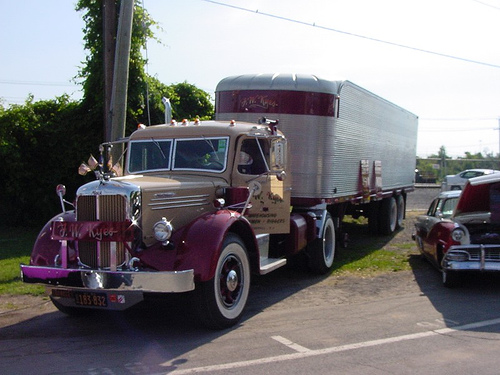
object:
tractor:
[17, 117, 293, 329]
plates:
[72, 291, 108, 308]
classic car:
[411, 172, 500, 289]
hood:
[450, 172, 499, 222]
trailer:
[213, 71, 421, 277]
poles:
[106, 0, 135, 179]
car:
[441, 167, 500, 193]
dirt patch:
[0, 264, 445, 342]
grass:
[1, 240, 417, 299]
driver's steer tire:
[190, 228, 256, 330]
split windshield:
[125, 134, 232, 176]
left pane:
[170, 136, 231, 174]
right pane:
[125, 137, 176, 175]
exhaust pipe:
[160, 96, 174, 126]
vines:
[0, 0, 215, 220]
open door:
[228, 131, 293, 236]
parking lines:
[146, 315, 499, 375]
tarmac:
[1, 290, 500, 375]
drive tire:
[284, 209, 339, 277]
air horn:
[256, 115, 276, 127]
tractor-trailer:
[19, 72, 419, 329]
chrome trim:
[147, 193, 211, 212]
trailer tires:
[367, 196, 397, 236]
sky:
[0, 0, 500, 160]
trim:
[126, 136, 230, 175]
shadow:
[1, 219, 405, 374]